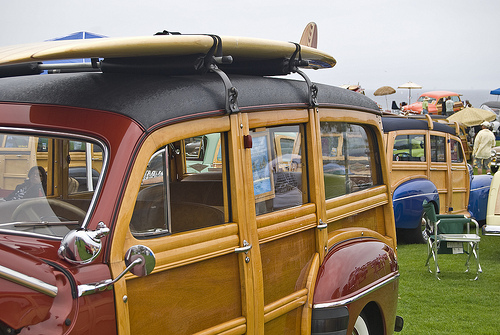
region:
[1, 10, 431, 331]
an old fashioned vehicle with a surfboard mounted on its roof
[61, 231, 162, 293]
side mirror of the car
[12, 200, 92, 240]
steering wheel of the car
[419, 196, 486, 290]
a lawn chair placed on the grass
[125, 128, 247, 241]
window of the car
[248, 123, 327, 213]
window of the car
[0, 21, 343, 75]
a large surfboard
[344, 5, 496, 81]
the sky is overcast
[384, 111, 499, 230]
an old fashioned automobile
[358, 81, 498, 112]
a bunch of beach umbrellas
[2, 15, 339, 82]
Cream colored surfboard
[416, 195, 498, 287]
Green fold up chair sitting in the grass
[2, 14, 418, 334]
Surfboard sitting on top of a car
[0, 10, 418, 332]
An old woody style car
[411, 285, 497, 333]
Green grass growing on the ground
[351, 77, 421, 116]
Umbrellas in the distance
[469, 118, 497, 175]
Man wearing a white baseball cap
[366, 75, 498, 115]
Ocean view in the distance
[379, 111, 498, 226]
An old blue and brown woody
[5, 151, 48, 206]
Woman wearing glasses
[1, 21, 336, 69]
A yellow-like surfboard.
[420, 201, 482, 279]
A green and white chair.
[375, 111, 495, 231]
A functioning automobile, with a tan paint job.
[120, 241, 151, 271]
A second mirror on the car.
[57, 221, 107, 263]
Another car mirror.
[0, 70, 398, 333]
A whole different car.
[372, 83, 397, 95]
A yellow umbrella.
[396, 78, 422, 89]
A different yellow umbrella.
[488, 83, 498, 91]
A blue umbrella.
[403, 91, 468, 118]
A red automobile.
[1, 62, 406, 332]
red, brown and black car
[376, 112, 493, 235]
blue, black and brown car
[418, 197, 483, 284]
green lawn chair between cars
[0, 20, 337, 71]
surfboard on roof of car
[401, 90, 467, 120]
orange car near umbrellas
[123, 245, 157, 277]
shiny silver mirror on side of car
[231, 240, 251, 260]
silver door handle on car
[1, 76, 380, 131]
black leather roof of car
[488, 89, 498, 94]
blue umbrella near orange car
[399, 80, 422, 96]
white umbrella near orange car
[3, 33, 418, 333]
Car is red and yellow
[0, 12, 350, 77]
Surfboard on top of car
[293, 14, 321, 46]
Fin of surfboard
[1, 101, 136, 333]
Front of car is red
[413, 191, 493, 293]
Fordable chair on the green grass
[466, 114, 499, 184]
Person wearing a white jacket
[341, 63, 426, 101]
Parasols are yellow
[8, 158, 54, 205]
Person can be seen behind the car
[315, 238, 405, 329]
Top of wheel is red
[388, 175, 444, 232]
Top of wheel is blue